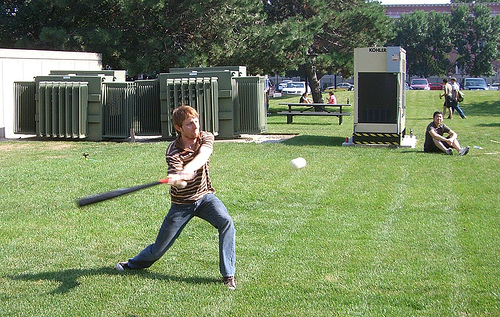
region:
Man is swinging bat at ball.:
[62, 70, 351, 288]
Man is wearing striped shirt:
[137, 85, 240, 285]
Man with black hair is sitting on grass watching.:
[407, 95, 474, 181]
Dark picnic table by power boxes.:
[273, 38, 381, 156]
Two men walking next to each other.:
[419, 58, 489, 130]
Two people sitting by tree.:
[279, 48, 350, 117]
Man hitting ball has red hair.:
[145, 95, 231, 181]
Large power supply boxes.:
[7, 34, 417, 147]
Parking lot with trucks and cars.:
[262, 51, 491, 108]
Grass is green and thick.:
[258, 133, 498, 313]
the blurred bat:
[75, 177, 172, 207]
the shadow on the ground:
[0, 266, 222, 296]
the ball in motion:
[291, 157, 306, 169]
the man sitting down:
[421, 110, 469, 154]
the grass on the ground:
[0, 89, 497, 314]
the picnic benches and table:
[277, 101, 349, 124]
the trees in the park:
[0, 0, 498, 112]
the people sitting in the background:
[297, 90, 335, 104]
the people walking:
[440, 77, 467, 120]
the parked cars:
[263, 77, 498, 95]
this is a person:
[125, 89, 249, 291]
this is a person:
[421, 109, 468, 177]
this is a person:
[435, 71, 462, 121]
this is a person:
[314, 82, 345, 116]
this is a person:
[277, 76, 321, 128]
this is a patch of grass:
[250, 199, 320, 271]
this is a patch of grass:
[378, 135, 430, 243]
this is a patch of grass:
[254, 225, 354, 313]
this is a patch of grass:
[35, 193, 97, 284]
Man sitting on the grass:
[421, 108, 470, 159]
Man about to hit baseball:
[70, 101, 249, 293]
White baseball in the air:
[285, 153, 310, 173]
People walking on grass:
[434, 72, 471, 118]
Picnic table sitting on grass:
[275, 95, 350, 127]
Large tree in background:
[445, 3, 498, 74]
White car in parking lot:
[277, 77, 307, 98]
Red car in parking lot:
[408, 75, 431, 91]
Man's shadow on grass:
[4, 260, 225, 298]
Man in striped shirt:
[74, 103, 241, 294]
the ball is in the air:
[289, 130, 337, 176]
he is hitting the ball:
[140, 98, 245, 289]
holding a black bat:
[62, 171, 183, 222]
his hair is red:
[167, 100, 203, 130]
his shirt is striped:
[170, 123, 211, 206]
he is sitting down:
[390, 108, 457, 183]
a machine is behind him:
[11, 44, 263, 146]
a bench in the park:
[272, 88, 353, 123]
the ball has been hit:
[252, 141, 318, 193]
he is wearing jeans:
[107, 193, 240, 300]